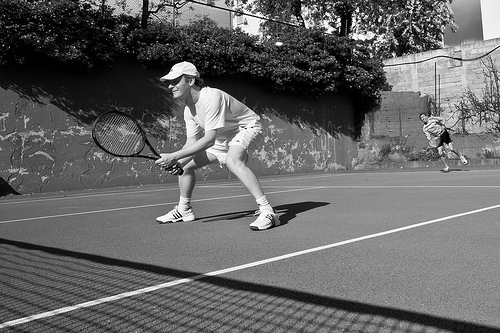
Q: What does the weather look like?
A: Clear.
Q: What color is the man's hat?
A: White.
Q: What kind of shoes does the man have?
A: Adidas.